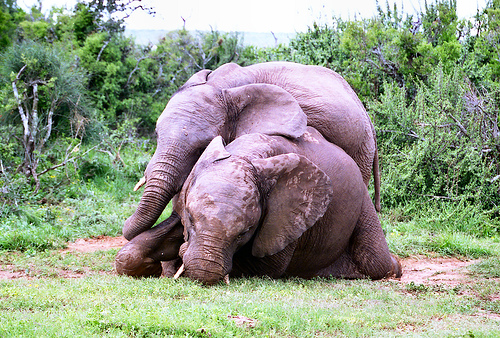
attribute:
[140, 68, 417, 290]
elephants — big, grey, playing, large, laying, fighting, happy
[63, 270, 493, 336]
grass — green, dirty, brown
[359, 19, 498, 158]
trees — green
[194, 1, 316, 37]
sky — white, clear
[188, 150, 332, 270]
elephant — grey, muddy, playing, sitting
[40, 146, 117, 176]
brances — small, brown